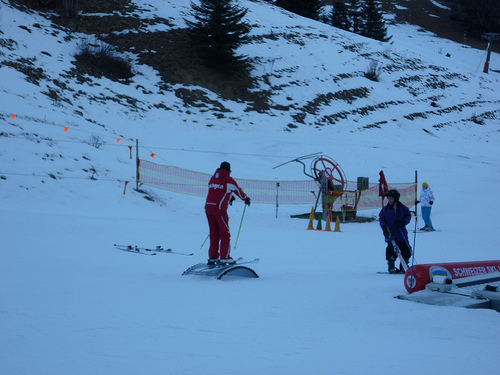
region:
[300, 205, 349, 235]
four cones on snow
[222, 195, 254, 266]
one ski pole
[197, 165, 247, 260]
red and white snow suit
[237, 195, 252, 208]
black glove on hand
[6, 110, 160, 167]
red flag on string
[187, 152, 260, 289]
person in snowsuit on semi circle surface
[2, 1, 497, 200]
snow covered hill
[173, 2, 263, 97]
evergreen tree in snow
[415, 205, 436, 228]
pair of blue snow pants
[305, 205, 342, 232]
cones on the mountain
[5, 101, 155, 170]
orange flags on the mountainside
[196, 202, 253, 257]
ski poles of the man wearing red and white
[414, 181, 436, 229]
skier wearing a white jacket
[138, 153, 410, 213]
orange safety netting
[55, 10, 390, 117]
grass patches in the snow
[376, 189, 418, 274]
skier wearing blue coat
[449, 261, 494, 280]
white lettering on red background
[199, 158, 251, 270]
skier in red suit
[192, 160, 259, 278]
skier balancing white skis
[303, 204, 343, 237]
yellow and green safety cones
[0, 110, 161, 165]
row of orange flags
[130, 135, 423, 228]
mesh fence safety barrier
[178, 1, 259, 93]
pine tree on snowy hillside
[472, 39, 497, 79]
pole on snowy hillside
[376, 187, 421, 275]
skier in blue snow suit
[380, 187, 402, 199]
black sports safety helmet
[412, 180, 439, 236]
skier in white coat and blue pants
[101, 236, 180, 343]
a ground covered in snow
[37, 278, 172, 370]
a white snow covering the ground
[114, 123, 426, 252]
a net in the snow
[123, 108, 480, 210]
poles in the snow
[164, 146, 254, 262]
a man wearing skies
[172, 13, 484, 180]
white snow covering the ground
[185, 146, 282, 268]
a man wearing a red jacket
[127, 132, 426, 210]
A net on poles.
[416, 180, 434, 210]
Person wearing a white jacket.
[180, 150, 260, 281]
A skier standing on barrel shaped object.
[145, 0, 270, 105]
A tree without snow.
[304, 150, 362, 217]
A large fan in the snow.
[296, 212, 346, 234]
Four orange safety cones.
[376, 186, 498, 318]
Person pulling something on wheels.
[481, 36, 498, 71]
Post in the background.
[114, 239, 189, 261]
Pair of skis in snow.